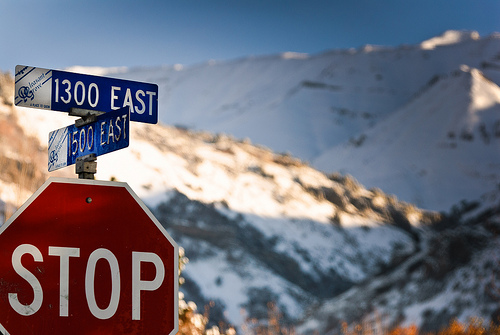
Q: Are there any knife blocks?
A: No, there are no knife blocks.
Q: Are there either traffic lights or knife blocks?
A: No, there are no knife blocks or traffic lights.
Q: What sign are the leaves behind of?
A: The leaves are behind the stop sign.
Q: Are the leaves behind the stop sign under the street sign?
A: Yes, the leaves are behind the stop sign.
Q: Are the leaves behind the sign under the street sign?
A: Yes, the leaves are behind the stop sign.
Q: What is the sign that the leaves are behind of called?
A: The sign is a street sign.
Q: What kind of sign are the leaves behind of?
A: The leaves are behind the street sign.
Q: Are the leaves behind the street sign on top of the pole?
A: Yes, the leaves are behind the street sign.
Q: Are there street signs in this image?
A: Yes, there is a street sign.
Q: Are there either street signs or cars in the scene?
A: Yes, there is a street sign.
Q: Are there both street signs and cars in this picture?
A: No, there is a street sign but no cars.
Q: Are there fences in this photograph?
A: No, there are no fences.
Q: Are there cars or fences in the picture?
A: No, there are no fences or cars.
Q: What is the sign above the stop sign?
A: The sign is a street sign.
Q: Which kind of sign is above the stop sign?
A: The sign is a street sign.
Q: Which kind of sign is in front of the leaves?
A: The sign is a street sign.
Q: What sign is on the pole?
A: The sign is a street sign.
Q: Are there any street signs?
A: Yes, there is a street sign.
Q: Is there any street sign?
A: Yes, there is a street sign.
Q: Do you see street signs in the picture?
A: Yes, there is a street sign.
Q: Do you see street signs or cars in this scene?
A: Yes, there is a street sign.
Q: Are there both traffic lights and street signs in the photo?
A: No, there is a street sign but no traffic lights.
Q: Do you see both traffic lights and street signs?
A: No, there is a street sign but no traffic lights.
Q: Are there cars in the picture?
A: No, there are no cars.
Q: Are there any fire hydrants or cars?
A: No, there are no cars or fire hydrants.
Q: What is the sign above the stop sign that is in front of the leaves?
A: The sign is a street sign.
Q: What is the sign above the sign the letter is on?
A: The sign is a street sign.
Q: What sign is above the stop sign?
A: The sign is a street sign.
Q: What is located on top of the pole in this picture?
A: The street sign is on top of the pole.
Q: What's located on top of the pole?
A: The street sign is on top of the pole.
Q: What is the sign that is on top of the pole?
A: The sign is a street sign.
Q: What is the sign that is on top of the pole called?
A: The sign is a street sign.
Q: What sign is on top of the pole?
A: The sign is a street sign.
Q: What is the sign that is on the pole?
A: The sign is a street sign.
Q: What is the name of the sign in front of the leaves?
A: The sign is a street sign.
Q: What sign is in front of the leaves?
A: The sign is a street sign.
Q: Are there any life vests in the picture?
A: No, there are no life vests.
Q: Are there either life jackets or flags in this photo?
A: No, there are no life jackets or flags.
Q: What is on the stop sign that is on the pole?
A: The letter is on the stop sign.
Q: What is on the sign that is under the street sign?
A: The letter is on the stop sign.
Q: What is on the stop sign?
A: The letter is on the stop sign.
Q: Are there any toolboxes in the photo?
A: No, there are no toolboxes.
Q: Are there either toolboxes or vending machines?
A: No, there are no toolboxes or vending machines.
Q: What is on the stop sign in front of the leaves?
A: The letter is on the stop sign.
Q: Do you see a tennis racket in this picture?
A: No, there are no rackets.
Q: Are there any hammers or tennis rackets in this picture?
A: No, there are no tennis rackets or hammers.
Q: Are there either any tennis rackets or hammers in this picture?
A: No, there are no tennis rackets or hammers.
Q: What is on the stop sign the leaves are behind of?
A: The letter is on the stop sign.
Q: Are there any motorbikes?
A: No, there are no motorbikes.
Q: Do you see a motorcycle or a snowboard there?
A: No, there are no motorcycles or snowboards.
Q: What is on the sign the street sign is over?
A: The letter is on the stop sign.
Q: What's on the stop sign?
A: The letter is on the stop sign.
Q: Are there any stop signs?
A: Yes, there is a stop sign.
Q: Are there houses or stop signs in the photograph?
A: Yes, there is a stop sign.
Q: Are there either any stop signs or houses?
A: Yes, there is a stop sign.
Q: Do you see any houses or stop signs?
A: Yes, there is a stop sign.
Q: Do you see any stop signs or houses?
A: Yes, there is a stop sign.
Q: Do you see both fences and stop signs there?
A: No, there is a stop sign but no fences.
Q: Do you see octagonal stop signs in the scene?
A: Yes, there is an octagonal stop sign.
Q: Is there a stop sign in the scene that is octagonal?
A: Yes, there is a stop sign that is octagonal.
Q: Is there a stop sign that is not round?
A: Yes, there is a octagonal stop sign.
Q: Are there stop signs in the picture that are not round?
A: Yes, there is a octagonal stop sign.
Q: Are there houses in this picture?
A: No, there are no houses.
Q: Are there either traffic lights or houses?
A: No, there are no houses or traffic lights.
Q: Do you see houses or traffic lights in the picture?
A: No, there are no houses or traffic lights.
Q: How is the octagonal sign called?
A: The sign is a stop sign.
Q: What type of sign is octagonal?
A: The sign is a stop sign.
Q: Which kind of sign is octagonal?
A: The sign is a stop sign.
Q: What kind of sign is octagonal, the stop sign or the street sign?
A: The stop sign is octagonal.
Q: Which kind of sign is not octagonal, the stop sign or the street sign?
A: The street sign is not octagonal.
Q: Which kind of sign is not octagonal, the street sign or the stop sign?
A: The street sign is not octagonal.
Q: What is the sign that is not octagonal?
A: The sign is a street sign.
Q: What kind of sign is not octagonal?
A: The sign is a street sign.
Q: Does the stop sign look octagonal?
A: Yes, the stop sign is octagonal.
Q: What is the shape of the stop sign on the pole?
A: The stop sign is octagonal.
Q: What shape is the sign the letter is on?
A: The stop sign is octagonal.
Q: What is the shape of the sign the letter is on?
A: The stop sign is octagonal.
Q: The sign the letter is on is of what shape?
A: The stop sign is octagonal.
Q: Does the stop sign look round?
A: No, the stop sign is octagonal.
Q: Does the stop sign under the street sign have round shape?
A: No, the stop sign is octagonal.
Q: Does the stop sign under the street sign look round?
A: No, the stop sign is octagonal.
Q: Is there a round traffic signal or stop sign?
A: No, there is a stop sign but it is octagonal.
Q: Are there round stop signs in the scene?
A: No, there is a stop sign but it is octagonal.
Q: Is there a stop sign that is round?
A: No, there is a stop sign but it is octagonal.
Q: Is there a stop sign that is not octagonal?
A: No, there is a stop sign but it is octagonal.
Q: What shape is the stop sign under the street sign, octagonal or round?
A: The stop sign is octagonal.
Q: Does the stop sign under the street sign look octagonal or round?
A: The stop sign is octagonal.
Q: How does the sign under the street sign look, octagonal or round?
A: The stop sign is octagonal.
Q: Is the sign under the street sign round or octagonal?
A: The stop sign is octagonal.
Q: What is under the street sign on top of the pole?
A: The stop sign is under the street sign.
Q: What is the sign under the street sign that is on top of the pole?
A: The sign is a stop sign.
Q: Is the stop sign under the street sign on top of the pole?
A: Yes, the stop sign is under the street sign.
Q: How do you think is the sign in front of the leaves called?
A: The sign is a stop sign.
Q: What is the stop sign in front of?
A: The stop sign is in front of the leaves.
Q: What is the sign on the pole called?
A: The sign is a stop sign.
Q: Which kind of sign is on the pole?
A: The sign is a stop sign.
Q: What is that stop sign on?
A: The stop sign is on the pole.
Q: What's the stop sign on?
A: The stop sign is on the pole.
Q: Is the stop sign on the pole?
A: Yes, the stop sign is on the pole.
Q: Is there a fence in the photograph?
A: No, there are no fences.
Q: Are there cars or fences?
A: No, there are no fences or cars.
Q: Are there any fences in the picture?
A: No, there are no fences.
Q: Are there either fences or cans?
A: No, there are no fences or cans.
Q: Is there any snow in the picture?
A: Yes, there is snow.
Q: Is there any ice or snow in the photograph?
A: Yes, there is snow.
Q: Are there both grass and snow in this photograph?
A: No, there is snow but no grass.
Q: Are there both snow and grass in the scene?
A: No, there is snow but no grass.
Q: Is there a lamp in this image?
A: No, there are no lamps.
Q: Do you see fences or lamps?
A: No, there are no lamps or fences.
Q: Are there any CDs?
A: No, there are no cds.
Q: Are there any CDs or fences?
A: No, there are no CDs or fences.